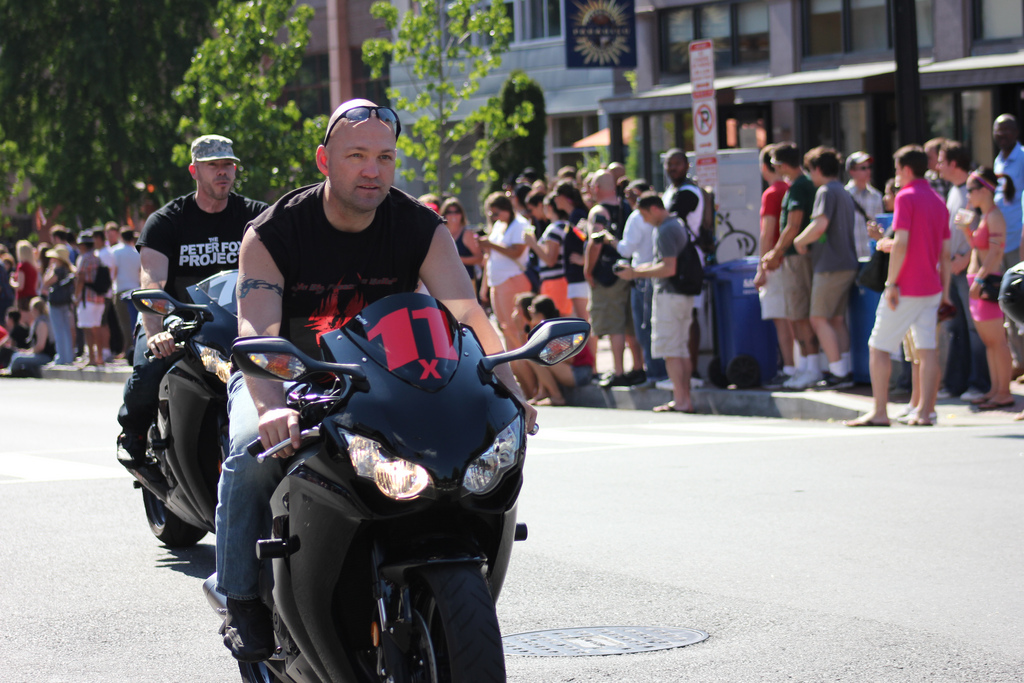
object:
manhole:
[565, 635, 621, 650]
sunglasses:
[325, 105, 404, 146]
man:
[843, 146, 953, 427]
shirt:
[892, 179, 951, 297]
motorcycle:
[117, 284, 238, 549]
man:
[117, 134, 271, 468]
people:
[473, 192, 537, 399]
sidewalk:
[592, 379, 990, 426]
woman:
[524, 191, 577, 318]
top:
[485, 211, 537, 287]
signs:
[691, 42, 717, 193]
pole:
[698, 187, 720, 385]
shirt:
[136, 191, 268, 320]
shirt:
[652, 217, 688, 295]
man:
[613, 195, 704, 413]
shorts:
[868, 287, 943, 353]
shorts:
[651, 288, 693, 359]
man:
[761, 143, 816, 390]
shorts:
[758, 255, 811, 321]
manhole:
[501, 626, 708, 657]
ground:
[0, 365, 1024, 683]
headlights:
[337, 427, 429, 501]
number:
[367, 307, 459, 380]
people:
[613, 195, 704, 414]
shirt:
[243, 182, 450, 393]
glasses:
[321, 105, 398, 146]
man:
[211, 98, 536, 664]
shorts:
[809, 269, 855, 319]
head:
[317, 99, 402, 211]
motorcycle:
[202, 293, 590, 682]